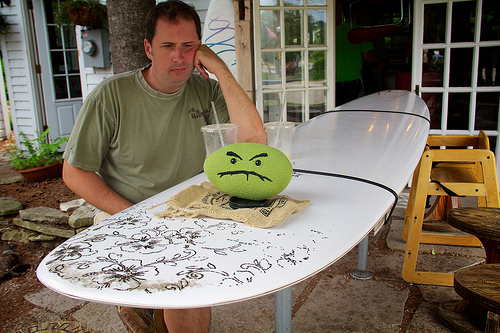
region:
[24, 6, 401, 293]
this is on a porch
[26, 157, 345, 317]
this is a surfboard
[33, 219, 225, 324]
the surfboard has flowers drawn on it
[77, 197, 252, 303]
the drawing is in black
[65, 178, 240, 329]
the surfboard is white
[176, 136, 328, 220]
this stone is painted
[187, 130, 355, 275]
the stone is painted green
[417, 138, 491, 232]
this is a childs stool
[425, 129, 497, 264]
this stool is yellow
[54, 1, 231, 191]
an adult male that looks grumpty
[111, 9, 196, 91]
the head of an adult male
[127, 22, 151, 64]
the ear of an adult male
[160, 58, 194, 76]
the mouth of an adult male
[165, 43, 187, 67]
the nose of an adult male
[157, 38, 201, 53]
the eyes of an adult male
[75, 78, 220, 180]
the green shorts of an adult male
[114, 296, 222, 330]
the leg of an adult male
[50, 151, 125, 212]
the arm of an adult male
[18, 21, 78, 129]
a small white back door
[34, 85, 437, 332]
Table made from surf board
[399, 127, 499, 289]
Child's high chair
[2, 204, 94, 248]
Stacked landscaping stones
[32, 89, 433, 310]
White surf board with black floral pattern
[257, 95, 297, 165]
Plastic cup with drinking straw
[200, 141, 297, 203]
Large nut with a face drawn on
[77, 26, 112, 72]
Outdoor electric meter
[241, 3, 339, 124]
Door with glass panels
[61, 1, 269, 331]
Man with a green shirt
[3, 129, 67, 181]
Red planter with vegetation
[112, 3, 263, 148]
Man resting his face on his hand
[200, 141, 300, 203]
A green ball with a mad face painted on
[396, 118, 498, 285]
Wooden child's high chair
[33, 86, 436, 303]
A large white floral surfboard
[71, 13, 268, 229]
Man in a green shirt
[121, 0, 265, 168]
Man who looks disappointed and upset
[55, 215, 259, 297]
Black tracing hibiscus flower print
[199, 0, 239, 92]
White surfboard with spiral design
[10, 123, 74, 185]
Potted plant at front doorway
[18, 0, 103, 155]
An open front door of a home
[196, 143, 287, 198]
green oval with angry face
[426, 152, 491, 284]
wooden high chair behind the surfboard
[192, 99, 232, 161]
clear plastic cup on the surfboard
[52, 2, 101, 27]
hanging plant over the meter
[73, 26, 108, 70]
electricity meter on the house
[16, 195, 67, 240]
stones on the ground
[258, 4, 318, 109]
reflection in the window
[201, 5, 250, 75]
surfboard against the wall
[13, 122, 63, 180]
potted plant by the door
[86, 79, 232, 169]
man wearing a green shirt